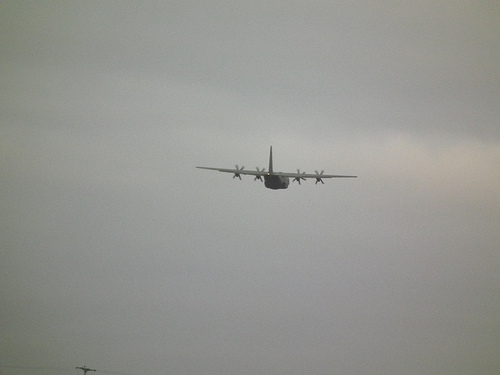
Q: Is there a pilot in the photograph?
A: No, there are no pilots.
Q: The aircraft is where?
A: The aircraft is in the sky.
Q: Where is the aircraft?
A: The aircraft is in the sky.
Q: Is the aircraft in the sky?
A: Yes, the aircraft is in the sky.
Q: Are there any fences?
A: No, there are no fences.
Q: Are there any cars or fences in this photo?
A: No, there are no fences or cars.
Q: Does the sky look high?
A: Yes, the sky is high.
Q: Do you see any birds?
A: No, there are no birds.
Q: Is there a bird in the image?
A: No, there are no birds.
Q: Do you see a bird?
A: No, there are no birds.